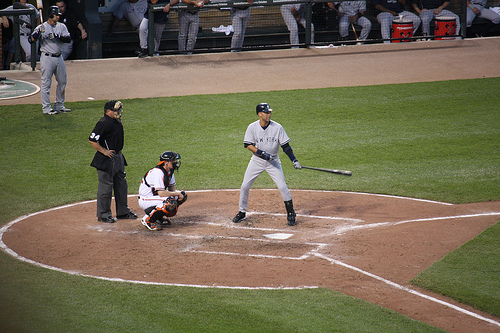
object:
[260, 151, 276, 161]
gloves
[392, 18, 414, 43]
cooler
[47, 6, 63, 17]
helmet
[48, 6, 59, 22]
mans head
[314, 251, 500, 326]
lines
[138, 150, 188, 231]
catcher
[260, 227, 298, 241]
home base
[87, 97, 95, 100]
spot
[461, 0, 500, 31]
people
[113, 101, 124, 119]
mask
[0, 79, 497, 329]
grass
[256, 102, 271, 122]
head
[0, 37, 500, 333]
floor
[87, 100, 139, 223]
man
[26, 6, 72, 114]
man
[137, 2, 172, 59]
man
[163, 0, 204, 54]
man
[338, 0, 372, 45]
man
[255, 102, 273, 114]
helmet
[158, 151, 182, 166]
helmet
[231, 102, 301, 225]
baseball player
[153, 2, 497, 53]
fence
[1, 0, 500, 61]
dugout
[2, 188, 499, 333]
dirt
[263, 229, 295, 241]
home plate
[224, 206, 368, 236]
batter's box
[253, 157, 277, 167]
crease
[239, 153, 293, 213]
pants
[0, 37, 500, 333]
field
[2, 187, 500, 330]
chalk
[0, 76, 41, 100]
deck circle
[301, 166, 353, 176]
bat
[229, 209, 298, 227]
shoes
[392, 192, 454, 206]
color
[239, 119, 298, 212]
dress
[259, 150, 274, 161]
hand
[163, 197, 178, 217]
pad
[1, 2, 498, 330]
stadium